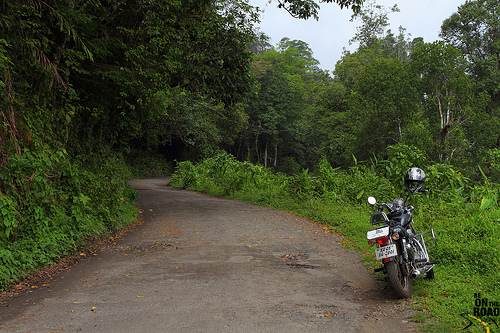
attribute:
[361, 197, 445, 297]
motorcycle — black